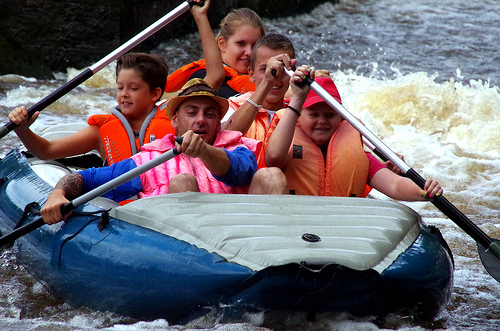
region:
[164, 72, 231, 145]
Man wearing a hat.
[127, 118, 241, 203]
Man wearing a pink life jacket.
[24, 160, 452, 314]
Blue and silver raft on the water.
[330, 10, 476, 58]
Churning water all around.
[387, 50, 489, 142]
White spray made because the water is forceful.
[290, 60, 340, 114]
Boy wearing a red hat.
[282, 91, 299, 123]
Young boy wearing a bracelet.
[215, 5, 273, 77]
Young girls smiling at the back of the raft.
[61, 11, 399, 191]
Five family members are rafting.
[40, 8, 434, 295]
people are rowing the boat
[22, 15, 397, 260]
people are rowing the boat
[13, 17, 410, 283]
people are rowing the boat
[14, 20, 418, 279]
people are rowing the boat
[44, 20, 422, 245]
people are rowing the boat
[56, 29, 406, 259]
people are wearing life vests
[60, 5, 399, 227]
people are wearing life vests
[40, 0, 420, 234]
people are wearing life vests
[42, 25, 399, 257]
people are wearing life vests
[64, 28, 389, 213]
people are wearing life vests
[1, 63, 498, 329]
white water river rapids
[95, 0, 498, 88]
calm section of the water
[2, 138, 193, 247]
silver and black oar handle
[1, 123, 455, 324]
grey and blue inflatable raft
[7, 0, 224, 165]
young boy with short brown hair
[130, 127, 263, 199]
pink life jacket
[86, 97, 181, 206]
bright orange and grey life jacket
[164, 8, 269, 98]
girl in the back of the raft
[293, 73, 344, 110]
red baseball hat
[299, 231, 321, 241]
inflation port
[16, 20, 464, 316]
Five people rafting in the rapids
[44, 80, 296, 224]
An adult man wearing a pink life jacket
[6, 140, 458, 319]
Blue and grey inflatable raft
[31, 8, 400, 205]
One girl and five males rafting in the water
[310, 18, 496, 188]
Turbulent water wave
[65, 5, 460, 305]
One adult and four children in the raft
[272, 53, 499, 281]
Black and silver paddle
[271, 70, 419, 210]
A boy wearing a red hat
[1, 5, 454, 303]
A group of people enjoying rafting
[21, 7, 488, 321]
People engaged in adventure sports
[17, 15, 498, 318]
people in blue raft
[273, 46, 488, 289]
boy holding boat paddle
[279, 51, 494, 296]
black and silver boat paddle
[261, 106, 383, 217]
boy wearing orange vest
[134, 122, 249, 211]
man wearing pink vest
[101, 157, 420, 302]
grey front on raft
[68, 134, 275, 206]
man wearing blue shirt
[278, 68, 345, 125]
boy wearing red hat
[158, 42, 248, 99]
girl wearing orange vest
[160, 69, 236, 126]
man wearing tan hat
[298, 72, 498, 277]
white and black oar in the water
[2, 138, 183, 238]
oar in the water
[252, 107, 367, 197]
bright orange puffy life jacket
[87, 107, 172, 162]
bright orange puffy life jacket